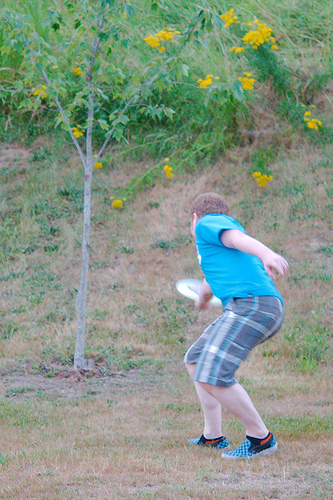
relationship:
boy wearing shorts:
[182, 191, 289, 462] [182, 295, 284, 388]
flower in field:
[196, 69, 218, 91] [10, 13, 310, 481]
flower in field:
[69, 66, 82, 77] [9, 15, 323, 354]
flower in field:
[196, 69, 218, 91] [9, 15, 323, 354]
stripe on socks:
[257, 434, 271, 443] [197, 433, 273, 446]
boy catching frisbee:
[182, 191, 289, 462] [175, 277, 222, 306]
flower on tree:
[196, 69, 218, 91] [0, 1, 190, 367]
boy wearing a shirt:
[182, 191, 289, 462] [194, 212, 267, 299]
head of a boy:
[188, 192, 229, 234] [186, 191, 293, 462]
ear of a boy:
[191, 210, 198, 225] [182, 191, 289, 462]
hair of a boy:
[179, 191, 291, 461] [189, 190, 228, 235]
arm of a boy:
[198, 214, 289, 278] [182, 191, 289, 462]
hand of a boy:
[256, 247, 289, 278] [182, 191, 289, 462]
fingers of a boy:
[264, 257, 288, 278] [182, 191, 289, 462]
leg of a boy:
[197, 312, 269, 439] [182, 191, 289, 462]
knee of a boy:
[196, 358, 218, 391] [182, 191, 289, 462]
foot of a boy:
[221, 428, 279, 460] [182, 191, 289, 462]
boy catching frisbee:
[186, 191, 293, 462] [174, 276, 221, 305]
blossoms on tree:
[141, 6, 283, 95] [0, 1, 190, 367]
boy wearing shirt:
[182, 191, 289, 462] [190, 210, 284, 302]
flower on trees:
[249, 164, 273, 189] [1, 2, 332, 373]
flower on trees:
[300, 107, 323, 132] [1, 2, 332, 373]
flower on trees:
[196, 69, 218, 91] [1, 2, 332, 373]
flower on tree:
[249, 164, 273, 189] [0, 1, 331, 376]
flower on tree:
[300, 107, 323, 132] [0, 1, 331, 376]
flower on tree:
[196, 69, 218, 91] [0, 1, 331, 376]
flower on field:
[249, 164, 273, 189] [0, 323, 329, 496]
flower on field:
[300, 107, 323, 132] [0, 323, 329, 496]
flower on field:
[196, 69, 218, 91] [0, 323, 329, 496]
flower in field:
[300, 107, 323, 132] [0, 323, 329, 496]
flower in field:
[249, 164, 273, 189] [0, 323, 329, 496]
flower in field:
[196, 69, 222, 92] [0, 323, 329, 496]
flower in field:
[301, 107, 325, 137] [0, 323, 329, 496]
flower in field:
[196, 69, 218, 91] [0, 323, 329, 496]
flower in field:
[69, 65, 81, 80] [0, 323, 329, 496]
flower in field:
[245, 24, 269, 50] [147, 39, 328, 198]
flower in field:
[196, 69, 218, 91] [158, 75, 316, 197]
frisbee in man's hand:
[170, 272, 229, 313] [187, 290, 216, 313]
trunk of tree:
[74, 161, 95, 376] [0, 4, 225, 412]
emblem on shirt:
[187, 242, 209, 264] [183, 210, 293, 307]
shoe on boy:
[173, 425, 232, 451] [182, 191, 289, 462]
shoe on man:
[211, 428, 283, 462] [153, 184, 297, 466]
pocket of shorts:
[226, 290, 250, 308] [192, 296, 293, 391]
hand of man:
[256, 247, 291, 282] [172, 185, 290, 464]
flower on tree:
[249, 164, 273, 189] [5, 80, 150, 389]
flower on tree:
[249, 164, 273, 189] [3, 3, 182, 392]